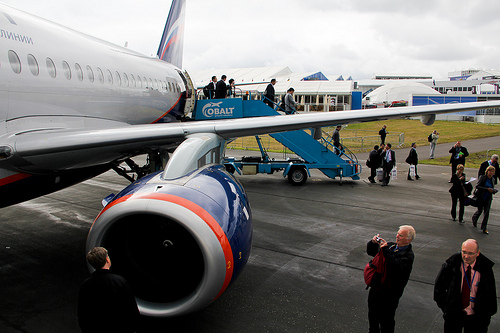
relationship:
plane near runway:
[4, 10, 497, 292] [3, 139, 499, 329]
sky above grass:
[9, 1, 499, 85] [214, 99, 499, 164]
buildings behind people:
[200, 62, 499, 128] [207, 73, 499, 321]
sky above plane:
[9, 1, 499, 85] [4, 10, 497, 292]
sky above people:
[9, 1, 499, 85] [207, 73, 499, 321]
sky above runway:
[9, 1, 499, 85] [3, 139, 499, 329]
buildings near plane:
[200, 62, 499, 128] [4, 10, 497, 292]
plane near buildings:
[4, 10, 497, 292] [200, 62, 499, 128]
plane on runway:
[4, 10, 497, 292] [3, 139, 499, 329]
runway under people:
[3, 139, 499, 329] [207, 73, 499, 321]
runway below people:
[3, 139, 499, 329] [207, 73, 499, 321]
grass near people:
[214, 99, 499, 164] [207, 73, 499, 321]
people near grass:
[207, 73, 499, 321] [214, 99, 499, 164]